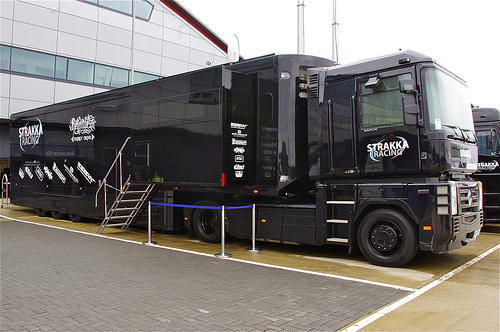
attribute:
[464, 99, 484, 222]
truck — large, black, touring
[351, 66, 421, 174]
door — side, passenger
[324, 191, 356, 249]
steps — passenger, side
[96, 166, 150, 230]
steps — side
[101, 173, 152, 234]
steps — metal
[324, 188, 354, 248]
steps — metal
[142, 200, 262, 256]
poles — silver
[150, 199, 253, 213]
rope — blue, barrier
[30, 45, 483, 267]
camper's — SIDE PULL OUT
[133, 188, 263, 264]
barricade — small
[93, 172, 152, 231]
stairs — pictured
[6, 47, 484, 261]
truck — white, black, large, touring, very big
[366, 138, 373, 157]
letter — white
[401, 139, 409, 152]
letter — white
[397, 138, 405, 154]
letter — white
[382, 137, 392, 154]
letter — white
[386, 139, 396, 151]
letter — white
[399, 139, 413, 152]
letter — white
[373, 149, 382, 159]
letter — white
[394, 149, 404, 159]
letter — white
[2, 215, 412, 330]
sidewalk — light gray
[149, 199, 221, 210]
cord — blue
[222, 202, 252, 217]
cord — blue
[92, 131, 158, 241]
steps — gray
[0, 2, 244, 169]
building — white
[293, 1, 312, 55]
pole — gray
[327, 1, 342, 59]
pole — gray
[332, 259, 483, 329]
line — white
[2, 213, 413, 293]
line — white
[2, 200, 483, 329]
lot — light brown